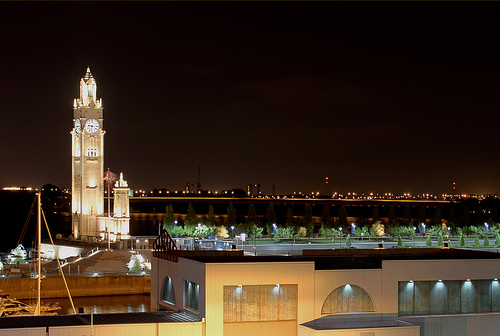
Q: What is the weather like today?
A: It is clear.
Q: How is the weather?
A: It is clear.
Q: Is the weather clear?
A: Yes, it is clear.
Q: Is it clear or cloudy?
A: It is clear.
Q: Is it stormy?
A: No, it is clear.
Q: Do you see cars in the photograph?
A: No, there are no cars.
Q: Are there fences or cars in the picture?
A: No, there are no cars or fences.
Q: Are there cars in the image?
A: No, there are no cars.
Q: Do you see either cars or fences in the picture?
A: No, there are no cars or fences.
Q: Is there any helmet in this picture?
A: No, there are no helmets.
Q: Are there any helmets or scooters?
A: No, there are no helmets or scooters.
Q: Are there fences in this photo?
A: No, there are no fences.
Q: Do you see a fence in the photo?
A: No, there are no fences.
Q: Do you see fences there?
A: No, there are no fences.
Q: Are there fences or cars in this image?
A: No, there are no fences or cars.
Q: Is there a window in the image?
A: Yes, there are windows.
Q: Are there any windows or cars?
A: Yes, there are windows.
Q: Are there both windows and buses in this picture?
A: No, there are windows but no buses.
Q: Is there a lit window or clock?
A: Yes, there are lit windows.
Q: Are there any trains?
A: No, there are no trains.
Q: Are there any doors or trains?
A: No, there are no trains or doors.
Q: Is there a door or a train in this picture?
A: No, there are no trains or doors.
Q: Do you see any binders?
A: No, there are no binders.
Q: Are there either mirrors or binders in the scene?
A: No, there are no binders or mirrors.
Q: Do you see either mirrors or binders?
A: No, there are no binders or mirrors.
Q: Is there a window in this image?
A: Yes, there is a window.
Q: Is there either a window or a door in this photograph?
A: Yes, there is a window.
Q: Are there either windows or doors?
A: Yes, there is a window.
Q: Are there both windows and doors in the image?
A: No, there is a window but no doors.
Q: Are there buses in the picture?
A: No, there are no buses.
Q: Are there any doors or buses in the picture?
A: No, there are no buses or doors.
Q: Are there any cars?
A: No, there are no cars.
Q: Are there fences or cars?
A: No, there are no cars or fences.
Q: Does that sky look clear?
A: Yes, the sky is clear.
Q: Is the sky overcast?
A: No, the sky is clear.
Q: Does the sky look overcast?
A: No, the sky is clear.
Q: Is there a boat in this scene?
A: Yes, there is a boat.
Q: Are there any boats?
A: Yes, there is a boat.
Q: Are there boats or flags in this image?
A: Yes, there is a boat.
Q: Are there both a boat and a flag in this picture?
A: Yes, there are both a boat and a flag.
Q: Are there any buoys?
A: No, there are no buoys.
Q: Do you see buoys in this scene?
A: No, there are no buoys.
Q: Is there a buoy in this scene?
A: No, there are no buoys.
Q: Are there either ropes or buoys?
A: No, there are no buoys or ropes.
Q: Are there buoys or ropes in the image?
A: No, there are no buoys or ropes.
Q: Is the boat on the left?
A: Yes, the boat is on the left of the image.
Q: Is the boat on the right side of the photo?
A: No, the boat is on the left of the image.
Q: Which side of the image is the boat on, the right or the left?
A: The boat is on the left of the image.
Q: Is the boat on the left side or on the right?
A: The boat is on the left of the image.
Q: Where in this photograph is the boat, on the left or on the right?
A: The boat is on the left of the image.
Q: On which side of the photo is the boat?
A: The boat is on the left of the image.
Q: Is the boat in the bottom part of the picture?
A: Yes, the boat is in the bottom of the image.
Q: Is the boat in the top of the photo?
A: No, the boat is in the bottom of the image.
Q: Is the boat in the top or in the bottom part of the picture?
A: The boat is in the bottom of the image.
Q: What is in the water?
A: The boat is in the water.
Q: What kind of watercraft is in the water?
A: The watercraft is a boat.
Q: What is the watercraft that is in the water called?
A: The watercraft is a boat.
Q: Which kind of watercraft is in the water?
A: The watercraft is a boat.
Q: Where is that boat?
A: The boat is in the water.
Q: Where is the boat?
A: The boat is in the water.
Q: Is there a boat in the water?
A: Yes, there is a boat in the water.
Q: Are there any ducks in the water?
A: No, there is a boat in the water.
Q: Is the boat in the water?
A: Yes, the boat is in the water.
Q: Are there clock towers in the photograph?
A: Yes, there is a clock tower.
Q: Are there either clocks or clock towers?
A: Yes, there is a clock tower.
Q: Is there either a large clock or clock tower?
A: Yes, there is a large clock tower.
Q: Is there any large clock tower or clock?
A: Yes, there is a large clock tower.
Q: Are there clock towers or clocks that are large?
A: Yes, the clock tower is large.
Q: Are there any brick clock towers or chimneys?
A: Yes, there is a brick clock tower.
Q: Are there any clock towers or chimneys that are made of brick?
A: Yes, the clock tower is made of brick.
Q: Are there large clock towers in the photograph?
A: Yes, there is a large clock tower.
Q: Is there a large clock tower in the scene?
A: Yes, there is a large clock tower.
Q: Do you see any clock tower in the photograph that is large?
A: Yes, there is a clock tower that is large.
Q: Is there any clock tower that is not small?
A: Yes, there is a large clock tower.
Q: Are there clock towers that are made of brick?
A: Yes, there is a clock tower that is made of brick.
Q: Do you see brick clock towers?
A: Yes, there is a clock tower that is made of brick.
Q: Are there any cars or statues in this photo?
A: No, there are no cars or statues.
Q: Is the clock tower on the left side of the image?
A: Yes, the clock tower is on the left of the image.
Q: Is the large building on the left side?
A: Yes, the clock tower is on the left of the image.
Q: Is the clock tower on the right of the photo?
A: No, the clock tower is on the left of the image.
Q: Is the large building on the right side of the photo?
A: No, the clock tower is on the left of the image.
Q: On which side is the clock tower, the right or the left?
A: The clock tower is on the left of the image.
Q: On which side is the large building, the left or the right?
A: The clock tower is on the left of the image.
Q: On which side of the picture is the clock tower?
A: The clock tower is on the left of the image.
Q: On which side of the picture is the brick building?
A: The clock tower is on the left of the image.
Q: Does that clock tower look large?
A: Yes, the clock tower is large.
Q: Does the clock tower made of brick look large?
A: Yes, the clock tower is large.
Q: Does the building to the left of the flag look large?
A: Yes, the clock tower is large.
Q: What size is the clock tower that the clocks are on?
A: The clock tower is large.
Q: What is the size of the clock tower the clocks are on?
A: The clock tower is large.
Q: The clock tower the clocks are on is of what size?
A: The clock tower is large.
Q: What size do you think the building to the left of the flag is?
A: The clock tower is large.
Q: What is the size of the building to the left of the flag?
A: The clock tower is large.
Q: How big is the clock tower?
A: The clock tower is large.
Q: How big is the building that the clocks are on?
A: The clock tower is large.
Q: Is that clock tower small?
A: No, the clock tower is large.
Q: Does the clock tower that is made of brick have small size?
A: No, the clock tower is large.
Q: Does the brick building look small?
A: No, the clock tower is large.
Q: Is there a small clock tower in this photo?
A: No, there is a clock tower but it is large.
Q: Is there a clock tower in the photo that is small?
A: No, there is a clock tower but it is large.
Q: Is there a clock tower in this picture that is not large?
A: No, there is a clock tower but it is large.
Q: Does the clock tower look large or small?
A: The clock tower is large.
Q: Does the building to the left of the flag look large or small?
A: The clock tower is large.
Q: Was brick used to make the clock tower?
A: Yes, the clock tower is made of brick.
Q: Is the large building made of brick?
A: Yes, the clock tower is made of brick.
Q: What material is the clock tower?
A: The clock tower is made of brick.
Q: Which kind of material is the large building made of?
A: The clock tower is made of brick.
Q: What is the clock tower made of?
A: The clock tower is made of brick.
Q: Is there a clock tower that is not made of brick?
A: No, there is a clock tower but it is made of brick.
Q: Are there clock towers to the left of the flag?
A: Yes, there is a clock tower to the left of the flag.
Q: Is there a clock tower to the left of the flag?
A: Yes, there is a clock tower to the left of the flag.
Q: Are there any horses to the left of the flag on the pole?
A: No, there is a clock tower to the left of the flag.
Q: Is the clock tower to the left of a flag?
A: Yes, the clock tower is to the left of a flag.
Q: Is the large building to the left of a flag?
A: Yes, the clock tower is to the left of a flag.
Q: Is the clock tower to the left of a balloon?
A: No, the clock tower is to the left of a flag.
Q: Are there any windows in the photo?
A: Yes, there is a window.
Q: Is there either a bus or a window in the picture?
A: Yes, there is a window.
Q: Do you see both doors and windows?
A: No, there is a window but no doors.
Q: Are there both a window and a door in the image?
A: No, there is a window but no doors.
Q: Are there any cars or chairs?
A: No, there are no cars or chairs.